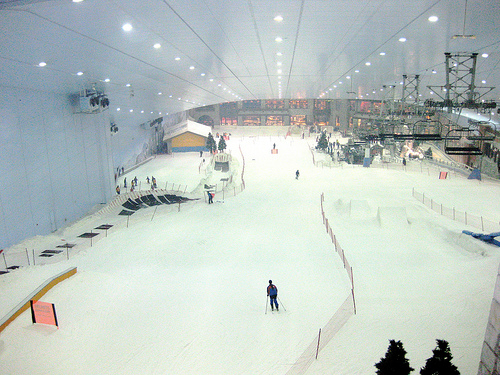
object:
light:
[275, 37, 282, 43]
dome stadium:
[0, 2, 500, 375]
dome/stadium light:
[153, 43, 161, 48]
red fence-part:
[351, 288, 356, 314]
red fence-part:
[293, 346, 314, 372]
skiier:
[264, 280, 286, 315]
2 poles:
[265, 294, 286, 315]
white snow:
[123, 256, 227, 368]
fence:
[278, 190, 357, 375]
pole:
[315, 328, 321, 360]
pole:
[351, 288, 356, 314]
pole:
[342, 249, 346, 268]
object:
[439, 171, 449, 180]